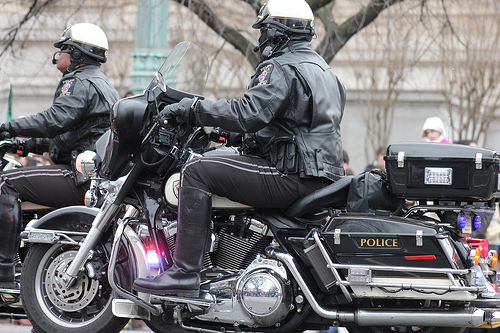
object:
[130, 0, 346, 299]
officer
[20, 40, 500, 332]
motorcycle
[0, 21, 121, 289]
officer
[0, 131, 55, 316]
motorcycle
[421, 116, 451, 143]
person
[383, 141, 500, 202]
case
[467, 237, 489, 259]
tail-light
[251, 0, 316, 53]
helmet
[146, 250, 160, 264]
light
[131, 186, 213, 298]
boot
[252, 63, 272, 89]
patch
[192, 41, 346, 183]
jacket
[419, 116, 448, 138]
hood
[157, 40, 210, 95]
windshield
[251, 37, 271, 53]
headset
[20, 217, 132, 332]
front-tire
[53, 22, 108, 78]
helmet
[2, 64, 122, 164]
jacket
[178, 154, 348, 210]
pants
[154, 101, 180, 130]
glove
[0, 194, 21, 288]
boot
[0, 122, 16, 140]
hand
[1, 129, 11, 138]
handle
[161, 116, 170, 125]
handle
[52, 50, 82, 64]
headset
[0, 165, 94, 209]
pants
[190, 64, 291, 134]
sleeve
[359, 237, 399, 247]
word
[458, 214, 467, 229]
light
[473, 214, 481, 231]
light